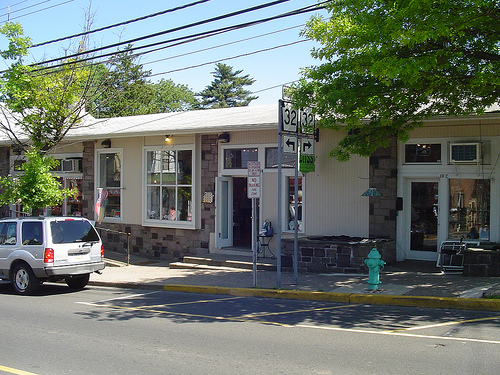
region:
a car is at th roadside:
[0, 172, 85, 298]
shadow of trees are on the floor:
[156, 260, 293, 349]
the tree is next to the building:
[389, 26, 491, 115]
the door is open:
[224, 185, 301, 236]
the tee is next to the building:
[20, 91, 72, 205]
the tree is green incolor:
[6, 80, 83, 205]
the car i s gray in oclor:
[8, 202, 111, 314]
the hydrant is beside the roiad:
[341, 238, 401, 308]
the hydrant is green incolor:
[351, 247, 395, 294]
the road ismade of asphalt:
[246, 317, 313, 373]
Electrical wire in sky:
[0, 0, 71, 24]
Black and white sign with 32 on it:
[277, 97, 299, 132]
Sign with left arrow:
[280, 133, 299, 153]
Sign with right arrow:
[298, 137, 315, 154]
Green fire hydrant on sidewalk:
[364, 247, 386, 284]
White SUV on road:
[0, 215, 104, 293]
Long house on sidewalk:
[1, 96, 498, 281]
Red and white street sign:
[246, 158, 262, 200]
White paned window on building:
[140, 141, 202, 231]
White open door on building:
[212, 167, 258, 252]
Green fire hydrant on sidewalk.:
[364, 245, 386, 292]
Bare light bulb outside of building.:
[165, 136, 171, 142]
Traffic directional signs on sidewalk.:
[278, 86, 316, 174]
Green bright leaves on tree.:
[0, 150, 84, 206]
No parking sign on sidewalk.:
[245, 155, 265, 284]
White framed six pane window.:
[140, 148, 200, 230]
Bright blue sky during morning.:
[50, 0, 109, 29]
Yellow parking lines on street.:
[90, 287, 465, 327]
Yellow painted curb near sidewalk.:
[163, 283, 413, 308]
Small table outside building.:
[257, 231, 277, 259]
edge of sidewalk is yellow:
[153, 271, 497, 323]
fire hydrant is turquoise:
[356, 241, 388, 293]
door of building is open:
[208, 143, 268, 260]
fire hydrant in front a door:
[341, 115, 498, 301]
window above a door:
[205, 143, 268, 253]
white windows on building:
[91, 140, 208, 241]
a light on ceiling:
[148, 130, 186, 151]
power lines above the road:
[1, 0, 463, 147]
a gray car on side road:
[3, 212, 110, 301]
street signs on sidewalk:
[272, 78, 327, 291]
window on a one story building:
[140, 146, 197, 226]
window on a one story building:
[94, 147, 119, 226]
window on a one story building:
[48, 152, 83, 222]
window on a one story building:
[402, 142, 440, 169]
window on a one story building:
[219, 145, 265, 171]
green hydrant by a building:
[362, 244, 386, 294]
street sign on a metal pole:
[241, 157, 264, 289]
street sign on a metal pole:
[272, 79, 319, 295]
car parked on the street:
[0, 210, 115, 302]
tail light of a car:
[39, 244, 55, 267]